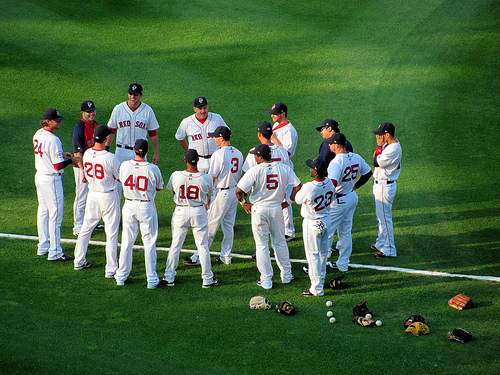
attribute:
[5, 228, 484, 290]
chalk — white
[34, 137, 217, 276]
uniforms — white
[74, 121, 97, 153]
jacket — red, blue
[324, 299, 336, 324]
baseballs — white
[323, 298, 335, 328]
baseballs — white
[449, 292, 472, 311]
glove — brown